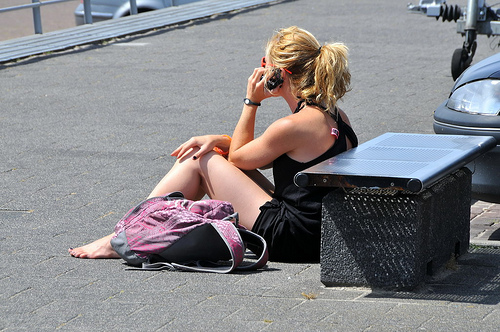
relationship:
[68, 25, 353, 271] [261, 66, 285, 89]
woman holds cell phone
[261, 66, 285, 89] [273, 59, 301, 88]
cell phone to ear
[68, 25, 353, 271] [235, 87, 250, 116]
woman wearing bracelet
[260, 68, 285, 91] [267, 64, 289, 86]
cell phone in ear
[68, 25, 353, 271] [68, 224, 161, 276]
woman has feet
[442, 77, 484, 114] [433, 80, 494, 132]
headlight of car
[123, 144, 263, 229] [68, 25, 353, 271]
leg of woman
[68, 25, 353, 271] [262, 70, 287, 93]
woman talking cell phone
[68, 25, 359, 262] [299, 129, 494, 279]
woman sitting bench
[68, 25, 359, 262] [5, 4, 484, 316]
woman sitting ground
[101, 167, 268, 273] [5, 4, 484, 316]
backpack on ground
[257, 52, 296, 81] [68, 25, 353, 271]
sunglasses on woman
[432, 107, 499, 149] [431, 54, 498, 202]
bumper of car